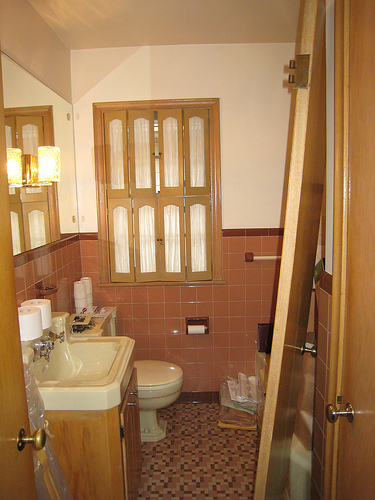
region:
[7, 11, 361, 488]
A bathroom scene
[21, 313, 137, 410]
This is the bathroom sink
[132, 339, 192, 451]
A commode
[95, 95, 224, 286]
The window is covered by shutters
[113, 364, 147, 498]
A cabinet is under the sink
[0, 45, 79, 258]
A mirror is on the wall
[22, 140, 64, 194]
A light is mounted on the mirror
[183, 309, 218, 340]
A toilet paper holder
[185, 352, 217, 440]
The floor and wall are tiled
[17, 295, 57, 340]
Rolls of toilet paper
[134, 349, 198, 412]
cover on white toilet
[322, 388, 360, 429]
metal knob on door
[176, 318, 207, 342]
toilet paper on holder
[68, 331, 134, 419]
square sink on cabinet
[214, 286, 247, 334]
pink tiles on wall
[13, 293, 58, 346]
two rolls of toilet paper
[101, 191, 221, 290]
closed shutters on window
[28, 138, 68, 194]
glowing light on wall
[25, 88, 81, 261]
mirror on bathroom wall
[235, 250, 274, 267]
rod on tile wall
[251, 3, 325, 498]
bathroom door off it's hinges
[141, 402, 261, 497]
multi colored bathroom tile floor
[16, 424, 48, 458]
gold door knob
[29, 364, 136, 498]
brown under sink bathroom cabinet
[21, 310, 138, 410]
white porcelain bathroom sink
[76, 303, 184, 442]
white porcelain toilet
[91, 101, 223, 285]
light brown wooden window frame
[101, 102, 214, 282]
eight paneled bathroom shutters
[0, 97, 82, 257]
bathroom mirror on wall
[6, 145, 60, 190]
bathroom light fixture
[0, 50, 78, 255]
Large bathroom mirror on wall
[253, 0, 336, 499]
Detached wood door leaning against wall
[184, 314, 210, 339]
Wood bathroom toilet paper holder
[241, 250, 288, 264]
White bathroom towel holder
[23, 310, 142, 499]
Single sink bathroom vanity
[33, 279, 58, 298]
Wood soap dish on wall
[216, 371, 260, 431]
Several items stacked and laying on floor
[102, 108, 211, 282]
Wood indoor window shutters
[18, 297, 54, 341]
Two rolls of toilet paper sitting on top of sink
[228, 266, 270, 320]
Ceramic tiled bathroom wall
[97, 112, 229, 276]
brown cabinet over toilet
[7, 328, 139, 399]
white sink in bathroom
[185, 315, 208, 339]
white toilet roll on holder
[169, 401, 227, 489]
brown and tile floor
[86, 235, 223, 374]
dark orange and tile wall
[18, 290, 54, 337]
white toilet roll on sink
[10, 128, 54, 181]
yellow lights over sink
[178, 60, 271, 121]
cream colored wall over toilet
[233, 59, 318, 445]
door is off hinge